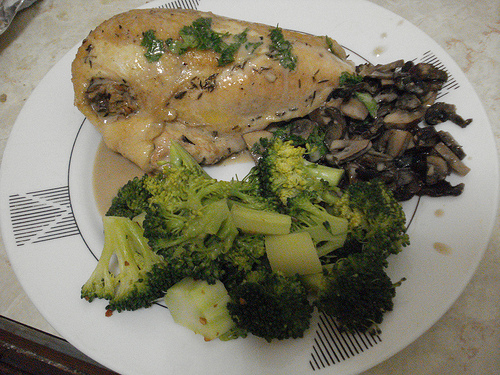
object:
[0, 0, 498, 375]
plate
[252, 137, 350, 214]
broccoli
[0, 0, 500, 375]
table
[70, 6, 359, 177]
chicken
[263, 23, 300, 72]
vegetables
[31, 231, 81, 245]
stripes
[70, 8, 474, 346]
food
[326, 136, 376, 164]
mushrooms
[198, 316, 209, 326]
pepper flakes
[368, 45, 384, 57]
oil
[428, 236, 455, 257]
oil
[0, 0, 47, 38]
napkin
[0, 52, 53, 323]
edge